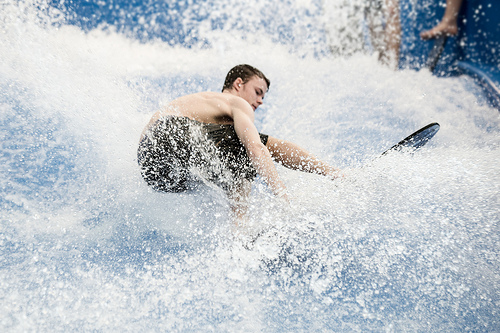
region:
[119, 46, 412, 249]
boy on surfboard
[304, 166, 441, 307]
white waves crashing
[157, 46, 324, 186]
boy not wearing a shirt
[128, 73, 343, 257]
boy bent over in water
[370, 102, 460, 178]
barely visible surfboard in water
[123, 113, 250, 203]
dark shorts on the surfer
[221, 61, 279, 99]
brown hair on the surfer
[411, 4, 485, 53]
foot near the water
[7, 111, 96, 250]
blue and white water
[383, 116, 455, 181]
tip of the board sticking out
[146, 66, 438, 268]
One boy is surfing.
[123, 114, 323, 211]
Boy is wearing black shorts.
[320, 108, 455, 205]
Surfing board is black color.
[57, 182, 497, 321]
Water is splashing.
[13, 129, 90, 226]
Water is blue color.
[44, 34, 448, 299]
Waves are white color.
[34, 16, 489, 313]
Day time picture.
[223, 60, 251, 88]
Boy hair is brown color.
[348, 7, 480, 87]
Person leg is seen in top corner.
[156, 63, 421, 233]
Boy is holding the surfing board with hands.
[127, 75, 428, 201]
The boy is surfboarding.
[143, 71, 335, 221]
The boy is in the water.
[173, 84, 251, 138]
The boy is topless.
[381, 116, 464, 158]
The surfboard is blue.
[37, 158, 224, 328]
The water is white and blue.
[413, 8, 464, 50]
A leg in the background.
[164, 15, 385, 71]
Splashes of water in the background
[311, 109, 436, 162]
The surfboard is in the water.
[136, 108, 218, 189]
The boy is wearing shorts.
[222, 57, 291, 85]
The boy hair is brown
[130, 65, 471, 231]
The man is surfing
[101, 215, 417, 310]
the sea water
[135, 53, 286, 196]
the young man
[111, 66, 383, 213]
the man is playing game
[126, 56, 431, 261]
the surfing game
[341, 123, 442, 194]
the surfing board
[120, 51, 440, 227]
the man is stunning in sea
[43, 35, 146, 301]
the sea water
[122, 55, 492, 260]
the man is training surfing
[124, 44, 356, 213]
man wearing swim suit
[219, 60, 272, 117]
the head of the boy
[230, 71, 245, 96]
the ear of the boy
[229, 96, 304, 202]
the arm of the boy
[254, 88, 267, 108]
the nose of the boy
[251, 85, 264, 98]
the eye of the boy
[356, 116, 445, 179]
a black surfboard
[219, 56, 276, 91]
the brown hair of th eboy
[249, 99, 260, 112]
the mouth of the boy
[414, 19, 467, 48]
the foot of a person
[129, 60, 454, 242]
a boy surfing